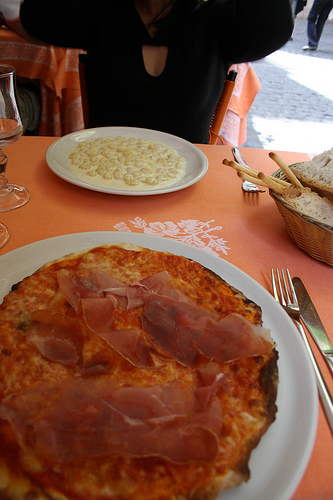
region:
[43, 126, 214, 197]
The plate is white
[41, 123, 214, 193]
The plate is round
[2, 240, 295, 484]
A round pizza with ham on top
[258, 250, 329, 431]
Silver fork and knife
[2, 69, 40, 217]
A clear empty glass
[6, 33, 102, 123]
Orange and white table cloth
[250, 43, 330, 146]
The ground is white cobblestones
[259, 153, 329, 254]
Brown woven basket on table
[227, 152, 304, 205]
Brown sticks in the dish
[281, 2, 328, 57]
People are walking on the cobblestone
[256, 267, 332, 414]
Stainless steel fork and knife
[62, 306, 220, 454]
Sliced ham on plate.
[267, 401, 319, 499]
White dinner plate.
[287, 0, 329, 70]
Person walking outside.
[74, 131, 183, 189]
A serving of cooked hominy on white plate.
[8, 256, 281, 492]
Pizza with ham.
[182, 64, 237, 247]
Orange and white tablecloth.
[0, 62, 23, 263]
Two goblet glasses.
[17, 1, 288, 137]
Dark brown chair at table.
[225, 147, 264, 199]
One stainless steel fork.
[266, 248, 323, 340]
A fork is visible.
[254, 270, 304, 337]
A fork is visible.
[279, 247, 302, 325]
A fork is visible.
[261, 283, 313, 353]
A fork is visible.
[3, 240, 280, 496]
flat bread with ham on top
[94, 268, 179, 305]
a slice of ham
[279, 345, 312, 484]
a white plate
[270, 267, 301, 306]
the tines of a fork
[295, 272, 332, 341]
the blade of a knife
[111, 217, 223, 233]
a flower pattern on a tablecloth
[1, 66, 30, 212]
a mostly empty wine glass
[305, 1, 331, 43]
a person's legs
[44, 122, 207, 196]
a plate of gnocchi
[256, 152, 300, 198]
bread sticks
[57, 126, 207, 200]
plate of food with sauce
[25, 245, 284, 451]
pizza on white plate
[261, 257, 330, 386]
fork and knife on table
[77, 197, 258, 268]
orange and white tablecloth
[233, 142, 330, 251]
bread products in basket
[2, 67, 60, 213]
glass on the table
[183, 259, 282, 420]
tomato sauce on pizza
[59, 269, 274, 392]
meat on top of pizza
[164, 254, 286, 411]
crust brown on edge of pizza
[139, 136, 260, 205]
fork next to plate of food